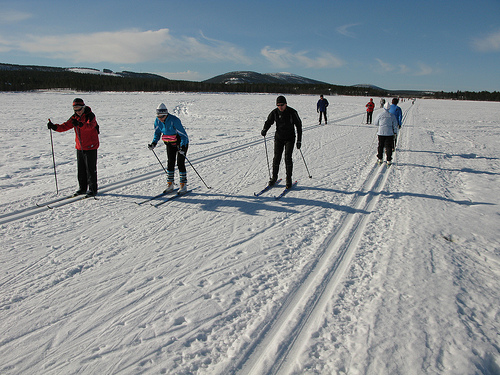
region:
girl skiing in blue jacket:
[144, 93, 188, 218]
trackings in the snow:
[266, 203, 418, 373]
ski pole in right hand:
[36, 107, 61, 222]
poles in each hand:
[141, 154, 223, 187]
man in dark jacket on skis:
[253, 73, 323, 254]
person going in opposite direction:
[367, 107, 393, 177]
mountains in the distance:
[215, 72, 315, 92]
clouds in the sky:
[55, 37, 160, 63]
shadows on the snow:
[421, 148, 491, 236]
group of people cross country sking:
[42, 71, 324, 211]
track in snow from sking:
[260, 214, 380, 357]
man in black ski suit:
[252, 74, 314, 214]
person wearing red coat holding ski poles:
[42, 97, 123, 194]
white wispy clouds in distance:
[21, 17, 356, 72]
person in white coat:
[369, 97, 403, 165]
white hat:
[144, 97, 176, 120]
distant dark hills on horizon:
[207, 55, 337, 95]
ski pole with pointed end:
[295, 142, 317, 184]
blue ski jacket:
[136, 113, 203, 159]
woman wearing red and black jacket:
[46, 91, 112, 206]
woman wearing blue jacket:
[138, 94, 199, 201]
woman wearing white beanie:
[140, 90, 206, 205]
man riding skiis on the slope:
[247, 87, 306, 209]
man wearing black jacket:
[252, 82, 314, 205]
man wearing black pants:
[248, 87, 313, 194]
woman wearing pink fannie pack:
[140, 99, 212, 202]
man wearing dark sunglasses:
[250, 83, 324, 193]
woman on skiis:
[135, 98, 207, 215]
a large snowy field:
[0, 92, 499, 374]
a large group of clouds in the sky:
[0, 27, 252, 63]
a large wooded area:
[0, 68, 499, 100]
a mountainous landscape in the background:
[0, 63, 435, 93]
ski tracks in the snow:
[231, 103, 413, 373]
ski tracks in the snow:
[0, 99, 407, 226]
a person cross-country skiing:
[47, 98, 99, 198]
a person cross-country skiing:
[260, 95, 302, 189]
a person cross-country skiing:
[147, 102, 188, 195]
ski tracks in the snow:
[238, 158, 398, 373]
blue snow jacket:
[150, 115, 188, 147]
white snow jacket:
[372, 109, 398, 136]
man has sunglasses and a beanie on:
[275, 95, 286, 114]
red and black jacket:
[55, 105, 100, 152]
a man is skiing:
[253, 95, 309, 203]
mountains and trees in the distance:
[0, 63, 397, 89]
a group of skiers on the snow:
[47, 85, 407, 207]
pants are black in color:
[73, 148, 101, 188]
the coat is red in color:
[53, 111, 109, 149]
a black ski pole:
[300, 145, 313, 180]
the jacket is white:
[375, 113, 397, 134]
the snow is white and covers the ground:
[0, 91, 499, 373]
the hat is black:
[272, 95, 288, 102]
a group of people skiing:
[51, 86, 324, 206]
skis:
[241, 171, 301, 212]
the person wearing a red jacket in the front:
[37, 90, 130, 200]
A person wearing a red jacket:
[43, 87, 119, 197]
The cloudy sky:
[1, 16, 498, 101]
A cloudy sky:
[2, 16, 498, 98]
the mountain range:
[5, 56, 498, 108]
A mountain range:
[6, 53, 498, 118]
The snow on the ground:
[4, 78, 499, 373]